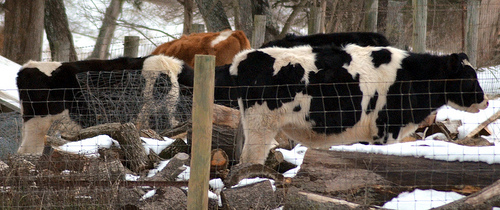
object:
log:
[319, 139, 499, 188]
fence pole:
[194, 54, 207, 209]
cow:
[231, 45, 491, 176]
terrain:
[278, 150, 500, 205]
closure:
[148, 51, 498, 165]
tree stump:
[31, 132, 133, 186]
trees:
[85, 13, 121, 61]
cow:
[16, 59, 239, 156]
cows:
[147, 29, 251, 70]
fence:
[7, 67, 497, 209]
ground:
[3, 130, 496, 208]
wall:
[236, 1, 499, 59]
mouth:
[471, 104, 486, 113]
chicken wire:
[5, 78, 499, 206]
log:
[210, 102, 245, 166]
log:
[223, 162, 287, 184]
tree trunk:
[0, 2, 46, 62]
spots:
[251, 39, 391, 121]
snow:
[0, 126, 499, 207]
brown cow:
[151, 30, 253, 68]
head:
[435, 50, 488, 112]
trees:
[460, 0, 482, 68]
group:
[12, 31, 492, 148]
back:
[293, 31, 385, 45]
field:
[4, 140, 497, 210]